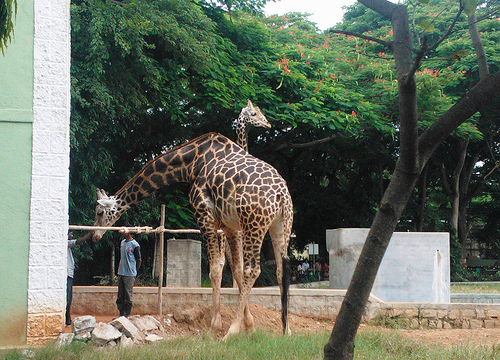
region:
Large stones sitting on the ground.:
[66, 310, 169, 350]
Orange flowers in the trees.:
[347, 108, 359, 119]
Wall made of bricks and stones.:
[373, 296, 498, 330]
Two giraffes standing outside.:
[80, 92, 312, 344]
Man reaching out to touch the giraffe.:
[66, 217, 96, 325]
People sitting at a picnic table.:
[287, 250, 332, 283]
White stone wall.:
[27, 55, 74, 322]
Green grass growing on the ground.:
[160, 332, 327, 358]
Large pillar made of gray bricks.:
[162, 232, 204, 290]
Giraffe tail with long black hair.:
[275, 250, 301, 342]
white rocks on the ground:
[57, 308, 169, 349]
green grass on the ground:
[17, 328, 497, 358]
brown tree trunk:
[320, 12, 495, 358]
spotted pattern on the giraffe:
[96, 98, 292, 332]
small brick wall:
[71, 283, 493, 330]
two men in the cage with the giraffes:
[68, 223, 139, 313]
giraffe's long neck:
[108, 132, 215, 230]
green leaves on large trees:
[75, 0, 498, 238]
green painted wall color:
[0, 3, 32, 335]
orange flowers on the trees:
[236, 10, 468, 127]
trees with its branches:
[151, 13, 469, 141]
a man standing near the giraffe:
[113, 222, 143, 316]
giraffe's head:
[78, 185, 120, 247]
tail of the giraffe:
[278, 230, 292, 332]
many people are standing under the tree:
[295, 255, 327, 277]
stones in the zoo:
[71, 313, 161, 351]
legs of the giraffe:
[200, 218, 296, 341]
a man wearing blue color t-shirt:
[118, 237, 143, 281]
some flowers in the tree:
[274, 33, 407, 131]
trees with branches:
[338, 55, 473, 215]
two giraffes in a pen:
[80, 100, 305, 335]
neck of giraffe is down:
[80, 125, 215, 260]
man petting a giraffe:
[65, 170, 146, 315]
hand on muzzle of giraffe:
[75, 186, 115, 246]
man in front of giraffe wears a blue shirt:
[57, 223, 99, 318]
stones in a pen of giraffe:
[54, 300, 168, 351]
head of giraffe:
[211, 93, 284, 161]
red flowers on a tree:
[266, 8, 466, 150]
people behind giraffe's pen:
[288, 244, 336, 289]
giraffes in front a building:
[13, 0, 297, 337]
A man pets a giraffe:
[66, 221, 108, 327]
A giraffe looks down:
[87, 131, 297, 349]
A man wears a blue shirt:
[117, 225, 147, 323]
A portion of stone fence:
[397, 302, 496, 328]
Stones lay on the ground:
[76, 317, 169, 345]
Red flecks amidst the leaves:
[273, 21, 353, 96]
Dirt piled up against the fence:
[215, 299, 290, 337]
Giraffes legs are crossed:
[229, 285, 269, 351]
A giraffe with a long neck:
[235, 96, 272, 156]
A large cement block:
[318, 224, 455, 308]